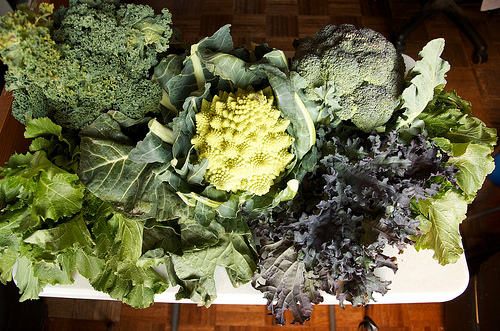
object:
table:
[0, 0, 445, 331]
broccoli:
[0, 0, 175, 136]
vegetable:
[255, 135, 472, 326]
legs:
[388, 0, 491, 66]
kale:
[2, 0, 172, 133]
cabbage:
[132, 26, 315, 219]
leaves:
[76, 25, 327, 252]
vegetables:
[0, 115, 173, 311]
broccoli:
[77, 22, 347, 310]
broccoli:
[292, 19, 406, 136]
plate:
[10, 213, 470, 306]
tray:
[7, 192, 467, 305]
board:
[14, 196, 466, 302]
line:
[35, 171, 86, 214]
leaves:
[255, 123, 460, 326]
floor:
[0, 0, 499, 331]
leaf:
[399, 38, 450, 128]